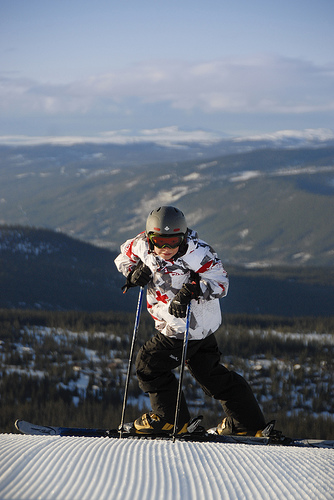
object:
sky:
[0, 0, 334, 127]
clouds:
[0, 52, 334, 136]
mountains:
[0, 144, 333, 250]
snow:
[66, 364, 98, 400]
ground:
[0, 315, 334, 436]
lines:
[29, 453, 298, 494]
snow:
[0, 434, 334, 500]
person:
[113, 204, 267, 434]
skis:
[14, 418, 296, 447]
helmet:
[145, 205, 187, 234]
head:
[145, 205, 188, 260]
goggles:
[149, 234, 185, 249]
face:
[154, 235, 180, 260]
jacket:
[113, 227, 230, 342]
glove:
[168, 282, 201, 319]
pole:
[169, 303, 193, 442]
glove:
[121, 264, 152, 294]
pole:
[117, 286, 144, 438]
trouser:
[134, 332, 265, 432]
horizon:
[0, 137, 334, 145]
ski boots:
[134, 411, 264, 437]